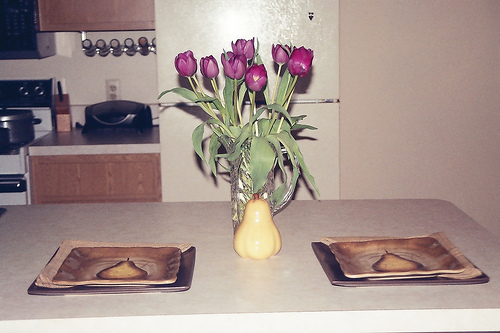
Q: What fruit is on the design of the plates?
A: Pears.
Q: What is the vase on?
A: A table.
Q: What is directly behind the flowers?
A: A refrigerator.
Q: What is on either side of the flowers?
A: Brown plates with pear prints on them.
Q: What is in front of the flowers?
A: A pear.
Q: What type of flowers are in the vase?
A: Tulips.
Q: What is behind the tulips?
A: A refrigerator.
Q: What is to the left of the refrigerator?
A: A counter.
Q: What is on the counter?
A: A black slow cooker.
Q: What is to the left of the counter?
A: A stove.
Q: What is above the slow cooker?
A: A spice rack.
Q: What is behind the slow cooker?
A: An electrical outlet.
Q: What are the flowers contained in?
A: A vase.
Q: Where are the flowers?
A: In a vase.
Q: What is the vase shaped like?
A: A pear.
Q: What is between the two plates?
A: A pear vase with tulips.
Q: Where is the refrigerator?
A: Behind the table.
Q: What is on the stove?
A: A pot.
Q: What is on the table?
A: Two plates and a vase of flowers.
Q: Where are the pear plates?
A: On the table.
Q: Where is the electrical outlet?
A: Above the counter to the left of the refrigerator.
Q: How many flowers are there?
A: Seven.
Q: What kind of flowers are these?
A: Tulips.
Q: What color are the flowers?
A: Pink.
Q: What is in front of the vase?
A: A pear.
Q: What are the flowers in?
A: A vase.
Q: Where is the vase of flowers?
A: On the counter.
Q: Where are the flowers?
A: In a vase.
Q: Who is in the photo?
A: Nobody.